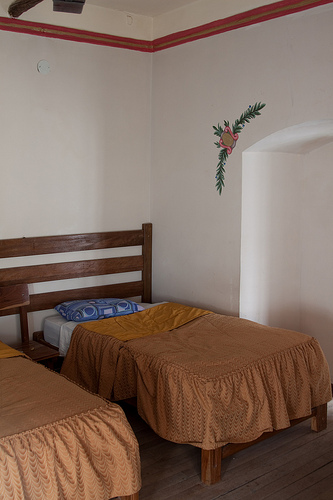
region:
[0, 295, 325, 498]
two beds in the room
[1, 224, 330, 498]
the beds are made of wood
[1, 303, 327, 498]
the bed sheets are beige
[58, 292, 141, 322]
pillow is blue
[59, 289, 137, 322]
the pillow has a pattern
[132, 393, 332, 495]
the floor is wood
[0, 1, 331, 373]
the walls are painted white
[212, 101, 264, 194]
a decal on the wall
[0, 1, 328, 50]
a red stripe on the wall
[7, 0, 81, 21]
a wood object on ceiling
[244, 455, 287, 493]
carpet is brown with stripes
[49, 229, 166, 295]
brown wooden headboard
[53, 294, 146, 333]
pillow is blue with a pattern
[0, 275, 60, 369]
brown wooden chair by beds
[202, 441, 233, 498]
brown wooden bed leg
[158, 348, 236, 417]
bedspread is orange and brown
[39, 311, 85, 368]
fitted sheet is white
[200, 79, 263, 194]
pineapple decoration on wall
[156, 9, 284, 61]
red and tan border on wall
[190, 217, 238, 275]
wall is bright white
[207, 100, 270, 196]
decal of a flower on a white wall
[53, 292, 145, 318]
a blue patterned pillow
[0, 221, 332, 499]
two twin beds on wooden frames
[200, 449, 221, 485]
the wooden leg of a twin bed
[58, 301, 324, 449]
a brown and golden blanket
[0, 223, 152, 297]
a wooden headboard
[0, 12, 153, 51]
red and gold paint on a wall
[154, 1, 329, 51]
red and gold stripes on a wall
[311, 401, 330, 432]
the wooden leg of a twin bed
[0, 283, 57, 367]
a wooden chair between twin beds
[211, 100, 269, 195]
green leaf symbol on the wall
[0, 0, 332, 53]
red and brown boarder near the ceiling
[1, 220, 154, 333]
brown, wood headboard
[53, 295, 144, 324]
blue and white pillow on the bed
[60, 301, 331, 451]
brown blanket on the bed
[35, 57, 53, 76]
white smoke alarm on the wall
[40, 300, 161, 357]
white sheet on the bed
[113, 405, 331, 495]
brown wood floor beneath the bed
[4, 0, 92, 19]
brown wood beams on the ceiling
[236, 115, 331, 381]
large indent in the wall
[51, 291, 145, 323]
A blue pillow is on the bed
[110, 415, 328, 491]
The floor is made of hard wood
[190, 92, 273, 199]
Artwork of a tree's leaves is on the wall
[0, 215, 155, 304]
Headboard is made of wood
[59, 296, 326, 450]
Bed sheet is brown in color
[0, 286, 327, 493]
Two beds in view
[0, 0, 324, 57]
A red and yellow stripe on the wall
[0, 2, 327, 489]
Photo was taken in the daytime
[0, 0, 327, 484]
Photo was taken indoors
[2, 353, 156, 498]
The lower half of the bed is in view